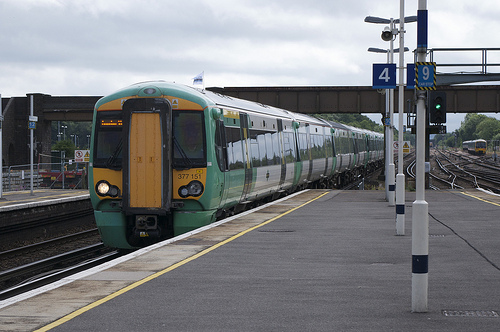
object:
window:
[172, 107, 207, 168]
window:
[91, 111, 128, 167]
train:
[86, 81, 385, 249]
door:
[129, 111, 162, 208]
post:
[411, 0, 428, 313]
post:
[396, 0, 405, 235]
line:
[0, 188, 333, 331]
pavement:
[0, 188, 499, 332]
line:
[458, 186, 500, 209]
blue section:
[411, 254, 429, 273]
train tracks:
[394, 146, 500, 193]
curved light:
[143, 88, 157, 95]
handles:
[137, 156, 153, 162]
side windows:
[215, 125, 385, 174]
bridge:
[0, 85, 499, 172]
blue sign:
[371, 63, 397, 89]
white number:
[378, 67, 391, 82]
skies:
[0, 0, 500, 98]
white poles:
[384, 0, 429, 313]